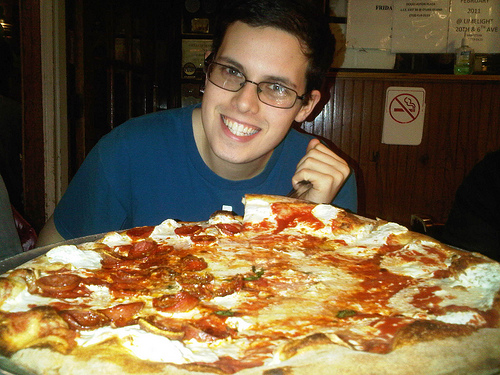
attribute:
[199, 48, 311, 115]
glasses — lead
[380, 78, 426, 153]
sign — red, white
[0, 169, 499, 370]
pizza — pepperoni, large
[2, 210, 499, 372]
pan — metal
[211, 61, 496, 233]
panelling — metal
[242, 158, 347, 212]
spatula — metal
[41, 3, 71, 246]
panel — white, wooden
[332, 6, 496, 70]
papers — white, laminated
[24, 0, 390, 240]
boy — smiling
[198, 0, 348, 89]
hair — dark, brown, short, curly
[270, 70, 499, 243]
wall — brown, wooden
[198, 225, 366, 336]
cheese — white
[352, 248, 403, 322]
sauce — red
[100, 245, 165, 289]
pepperoni — red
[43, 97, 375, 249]
shirt — blue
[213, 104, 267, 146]
smile — wide, big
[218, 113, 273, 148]
teeth — white, straight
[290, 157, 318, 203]
utensil — silver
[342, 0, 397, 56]
paper — laminated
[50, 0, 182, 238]
door — wooden